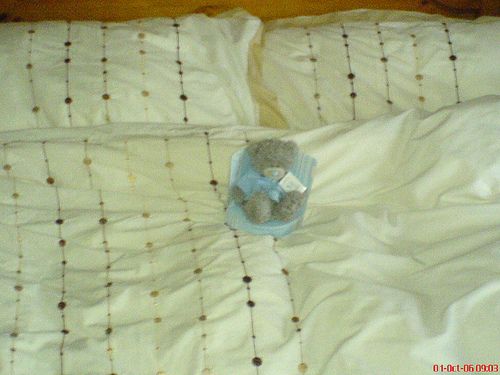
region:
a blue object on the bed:
[203, 139, 316, 234]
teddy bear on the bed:
[241, 134, 327, 226]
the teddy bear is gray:
[232, 123, 316, 236]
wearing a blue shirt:
[216, 145, 322, 234]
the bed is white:
[2, 10, 458, 351]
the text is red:
[428, 360, 498, 372]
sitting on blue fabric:
[232, 140, 320, 255]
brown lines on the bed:
[23, 34, 235, 342]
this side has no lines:
[298, 133, 492, 373]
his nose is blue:
[269, 165, 279, 180]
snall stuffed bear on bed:
[222, 131, 322, 238]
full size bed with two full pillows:
[1, 8, 496, 370]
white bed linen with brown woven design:
[2, 115, 317, 365]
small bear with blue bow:
[223, 132, 323, 242]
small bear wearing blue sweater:
[225, 131, 315, 239]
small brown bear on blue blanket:
[226, 135, 321, 235]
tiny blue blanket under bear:
[222, 138, 317, 238]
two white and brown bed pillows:
[0, 0, 496, 133]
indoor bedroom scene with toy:
[11, 0, 497, 363]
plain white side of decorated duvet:
[283, 96, 498, 362]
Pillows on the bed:
[90, 45, 260, 102]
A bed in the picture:
[90, 166, 190, 287]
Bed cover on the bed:
[123, 245, 272, 343]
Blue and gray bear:
[227, 125, 303, 232]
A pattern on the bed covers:
[118, 123, 220, 286]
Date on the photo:
[431, 338, 497, 373]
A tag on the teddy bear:
[277, 168, 312, 201]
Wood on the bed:
[108, 3, 211, 25]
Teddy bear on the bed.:
[219, 138, 313, 230]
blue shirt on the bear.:
[233, 139, 288, 205]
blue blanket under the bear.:
[224, 136, 318, 238]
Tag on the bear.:
[275, 169, 310, 200]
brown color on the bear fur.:
[226, 136, 304, 231]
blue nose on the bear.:
[265, 160, 284, 180]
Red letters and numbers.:
[426, 353, 498, 374]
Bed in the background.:
[2, 10, 499, 374]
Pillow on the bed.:
[0, 12, 258, 134]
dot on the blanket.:
[236, 269, 257, 286]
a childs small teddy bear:
[228, 132, 306, 243]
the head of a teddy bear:
[240, 133, 298, 174]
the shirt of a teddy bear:
[231, 169, 289, 200]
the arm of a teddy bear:
[230, 178, 252, 203]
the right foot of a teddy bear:
[240, 192, 277, 229]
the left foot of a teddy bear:
[278, 193, 300, 213]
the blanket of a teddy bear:
[235, 196, 256, 233]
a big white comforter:
[331, 98, 483, 300]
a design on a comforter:
[41, 195, 151, 322]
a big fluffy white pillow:
[264, 21, 446, 118]